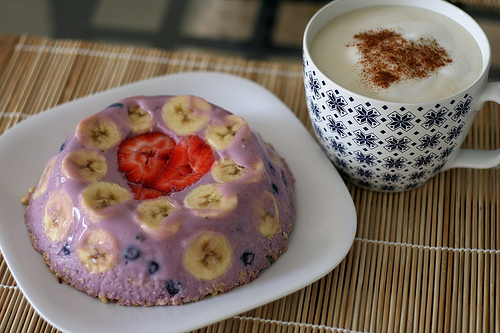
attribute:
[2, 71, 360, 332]
plate — square, sitting, white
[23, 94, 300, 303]
desert — breakfast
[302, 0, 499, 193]
cup — white, flowery, coffee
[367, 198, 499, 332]
platemat — brown, bamboo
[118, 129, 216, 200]
cherry — center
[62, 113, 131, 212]
bananas — sliced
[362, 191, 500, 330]
placemat — wicker, bamboo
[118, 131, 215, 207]
strawberry — sliced